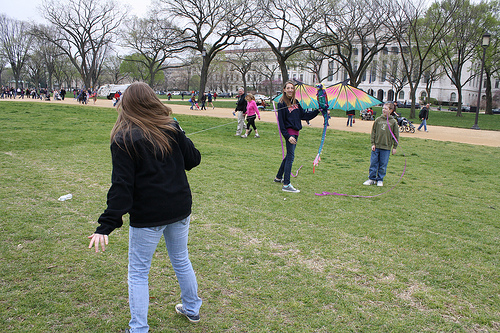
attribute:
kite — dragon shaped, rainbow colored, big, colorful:
[272, 71, 384, 177]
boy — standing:
[362, 102, 399, 191]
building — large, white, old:
[163, 14, 497, 112]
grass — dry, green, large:
[3, 99, 499, 331]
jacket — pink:
[245, 100, 262, 117]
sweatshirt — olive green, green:
[372, 114, 402, 152]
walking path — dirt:
[3, 90, 499, 164]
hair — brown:
[107, 81, 181, 159]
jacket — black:
[89, 123, 202, 236]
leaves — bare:
[150, 1, 265, 55]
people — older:
[234, 87, 264, 138]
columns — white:
[356, 45, 426, 83]